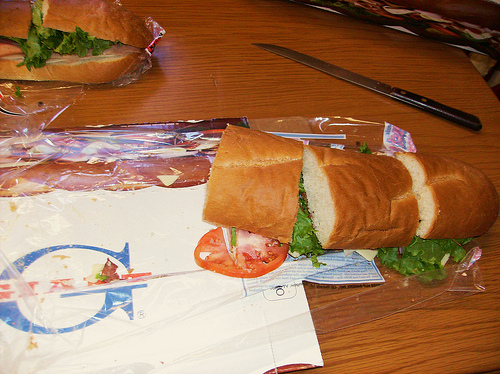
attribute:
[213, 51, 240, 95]
table — brown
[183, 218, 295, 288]
tomato — orange, round, red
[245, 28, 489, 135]
knife — black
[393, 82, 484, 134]
handle — black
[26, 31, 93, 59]
vegetables — green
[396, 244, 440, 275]
lettuce — green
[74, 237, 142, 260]
paper — blue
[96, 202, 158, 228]
paper — white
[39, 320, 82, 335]
box — blue, white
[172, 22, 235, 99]
table top — brown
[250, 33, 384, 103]
blade — sharp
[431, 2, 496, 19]
bread — brown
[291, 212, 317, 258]
leafy stuffing — green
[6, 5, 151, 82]
sandwich — large